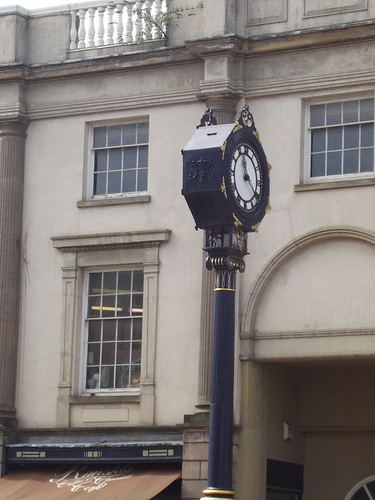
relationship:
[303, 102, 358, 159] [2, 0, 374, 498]
window on building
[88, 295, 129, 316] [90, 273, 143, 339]
light hanging on wall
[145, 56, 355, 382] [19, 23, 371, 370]
clock in front of building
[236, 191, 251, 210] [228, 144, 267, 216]
numerals are on clock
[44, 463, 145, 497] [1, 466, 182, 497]
writing on awning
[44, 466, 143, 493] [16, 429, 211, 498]
text on awning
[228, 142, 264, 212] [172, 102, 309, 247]
clock face on clock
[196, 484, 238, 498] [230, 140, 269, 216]
trimming on clock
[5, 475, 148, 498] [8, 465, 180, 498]
fabric on awning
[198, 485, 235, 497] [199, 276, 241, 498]
stripes are on pole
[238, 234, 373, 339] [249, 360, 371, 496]
arch over entryway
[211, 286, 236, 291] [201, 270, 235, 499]
stripe around pole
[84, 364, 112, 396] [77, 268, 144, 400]
fan seen in window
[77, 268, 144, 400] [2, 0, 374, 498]
window on building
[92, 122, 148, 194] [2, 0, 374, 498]
small window on building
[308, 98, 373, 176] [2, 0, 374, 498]
window on building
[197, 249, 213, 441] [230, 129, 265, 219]
column behind clock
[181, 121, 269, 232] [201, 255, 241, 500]
clock on clock post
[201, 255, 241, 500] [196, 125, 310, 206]
clock post on clock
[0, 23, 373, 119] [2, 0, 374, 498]
part on building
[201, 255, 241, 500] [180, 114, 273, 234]
clock post holding clock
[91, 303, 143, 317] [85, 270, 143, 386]
lights are inside window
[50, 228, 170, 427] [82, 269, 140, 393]
windowdesign are around window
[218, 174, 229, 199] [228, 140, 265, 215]
details are on clockface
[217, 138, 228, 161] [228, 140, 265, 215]
details are on clockface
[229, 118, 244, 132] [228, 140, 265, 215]
details are on clockface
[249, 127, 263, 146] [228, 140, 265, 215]
details are on clockface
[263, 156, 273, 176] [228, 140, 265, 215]
details are on clockface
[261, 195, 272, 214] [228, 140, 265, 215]
details are on clockface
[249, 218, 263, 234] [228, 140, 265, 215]
details are on clockface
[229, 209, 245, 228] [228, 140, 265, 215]
details are on clockface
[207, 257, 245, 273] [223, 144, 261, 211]
gold scrolls are under clock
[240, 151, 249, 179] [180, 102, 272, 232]
hand on clock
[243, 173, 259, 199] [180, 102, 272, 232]
hand on clock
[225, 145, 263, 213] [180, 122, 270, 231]
numerals are on clock